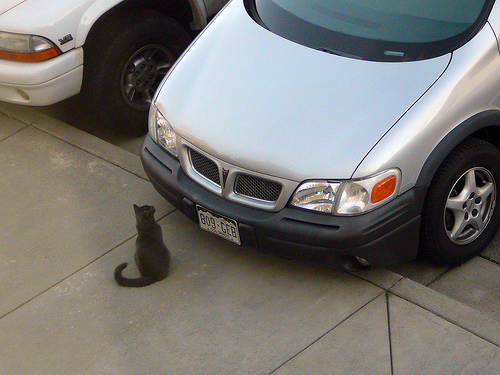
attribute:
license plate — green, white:
[199, 204, 244, 244]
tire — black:
[407, 112, 497, 282]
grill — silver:
[176, 153, 296, 225]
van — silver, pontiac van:
[144, 2, 496, 284]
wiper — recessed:
[322, 37, 368, 79]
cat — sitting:
[110, 197, 187, 298]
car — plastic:
[132, 7, 499, 283]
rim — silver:
[444, 167, 499, 245]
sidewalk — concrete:
[0, 107, 146, 373]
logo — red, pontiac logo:
[206, 156, 236, 211]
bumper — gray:
[140, 132, 421, 270]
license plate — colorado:
[187, 198, 252, 263]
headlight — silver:
[287, 185, 354, 217]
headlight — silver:
[282, 176, 373, 219]